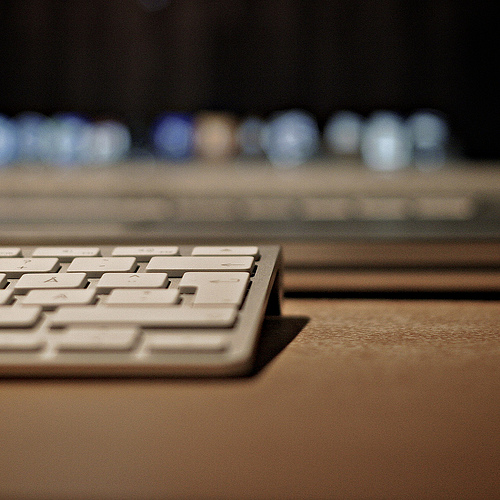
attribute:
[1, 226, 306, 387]
keyboard — key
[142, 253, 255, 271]
key — arrow, long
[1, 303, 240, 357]
keys — out of focus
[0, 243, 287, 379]
keyboard — key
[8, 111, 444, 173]
objects — blue and orange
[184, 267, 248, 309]
key — enter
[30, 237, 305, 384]
keyboard — key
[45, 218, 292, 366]
keyboard — key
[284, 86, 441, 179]
objects — blurry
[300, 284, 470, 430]
surface — shiny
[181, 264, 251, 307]
key — out of focus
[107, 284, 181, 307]
key — out of focus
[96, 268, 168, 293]
key — out of focus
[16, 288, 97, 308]
key — out of focus